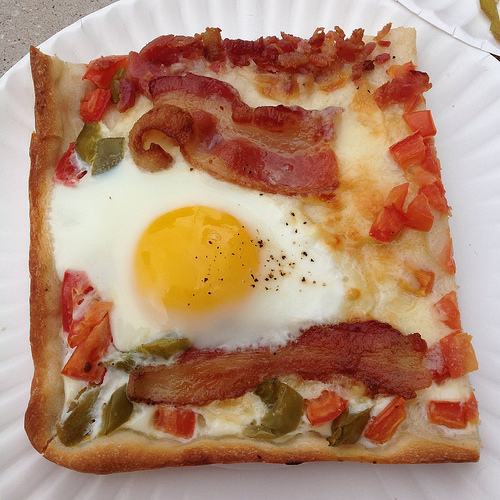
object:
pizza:
[23, 20, 480, 477]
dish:
[0, 0, 500, 500]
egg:
[46, 152, 345, 354]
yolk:
[134, 203, 261, 317]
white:
[65, 189, 134, 246]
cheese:
[342, 101, 389, 199]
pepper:
[76, 346, 123, 440]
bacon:
[127, 69, 346, 204]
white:
[440, 53, 499, 135]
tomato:
[389, 127, 429, 170]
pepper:
[186, 211, 326, 307]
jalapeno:
[76, 125, 124, 177]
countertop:
[0, 0, 121, 79]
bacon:
[128, 31, 389, 79]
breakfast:
[0, 0, 499, 500]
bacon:
[123, 319, 431, 406]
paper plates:
[391, 1, 500, 60]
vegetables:
[78, 88, 112, 123]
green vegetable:
[244, 374, 305, 443]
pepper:
[56, 143, 88, 189]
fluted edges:
[74, 1, 432, 22]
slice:
[21, 302, 160, 472]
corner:
[23, 378, 126, 477]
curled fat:
[127, 74, 193, 174]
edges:
[407, 26, 484, 469]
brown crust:
[22, 45, 80, 479]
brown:
[326, 189, 370, 249]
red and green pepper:
[243, 378, 408, 447]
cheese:
[340, 246, 404, 318]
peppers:
[120, 394, 472, 452]